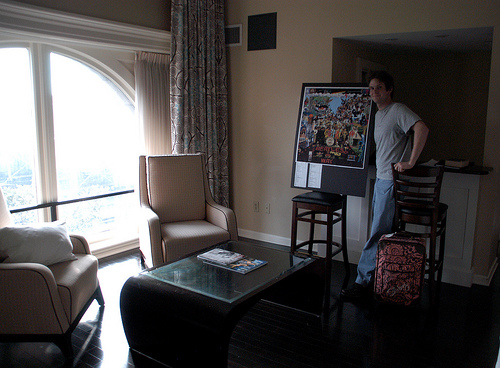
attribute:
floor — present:
[0, 235, 498, 367]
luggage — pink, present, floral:
[372, 231, 426, 312]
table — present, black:
[122, 237, 328, 367]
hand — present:
[394, 160, 414, 171]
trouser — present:
[354, 177, 394, 286]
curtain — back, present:
[133, 51, 171, 157]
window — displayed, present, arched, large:
[0, 44, 140, 245]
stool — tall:
[390, 162, 448, 293]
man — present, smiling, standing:
[339, 67, 428, 300]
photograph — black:
[290, 83, 373, 196]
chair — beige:
[138, 151, 239, 271]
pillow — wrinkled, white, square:
[0, 219, 76, 267]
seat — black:
[292, 191, 344, 208]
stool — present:
[290, 190, 350, 315]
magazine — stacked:
[196, 246, 245, 267]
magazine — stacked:
[203, 254, 268, 273]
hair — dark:
[365, 69, 396, 99]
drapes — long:
[169, 2, 231, 212]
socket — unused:
[253, 201, 260, 213]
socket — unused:
[263, 203, 270, 214]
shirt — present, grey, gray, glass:
[372, 102, 420, 180]